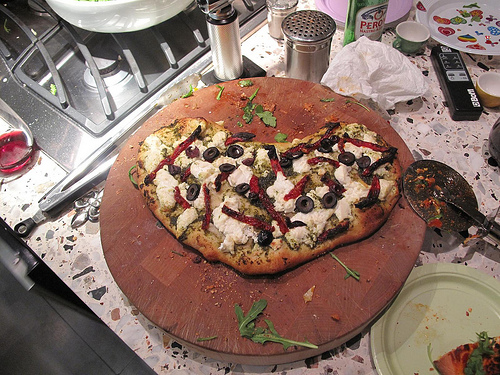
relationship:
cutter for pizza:
[394, 152, 499, 249] [130, 106, 410, 282]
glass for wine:
[1, 99, 45, 202] [1, 129, 38, 177]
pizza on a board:
[130, 106, 410, 282] [91, 73, 436, 371]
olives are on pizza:
[201, 141, 243, 173] [130, 106, 410, 282]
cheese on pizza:
[336, 162, 363, 215] [130, 106, 410, 282]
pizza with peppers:
[130, 106, 410, 282] [249, 180, 288, 232]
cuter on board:
[394, 152, 499, 249] [91, 73, 436, 371]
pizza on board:
[130, 106, 410, 282] [91, 73, 436, 371]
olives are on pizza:
[294, 187, 341, 218] [130, 106, 410, 282]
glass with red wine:
[1, 99, 45, 202] [1, 129, 38, 177]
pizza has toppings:
[130, 106, 410, 282] [163, 137, 385, 228]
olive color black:
[234, 175, 260, 205] [234, 180, 256, 200]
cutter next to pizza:
[394, 152, 499, 249] [130, 106, 410, 282]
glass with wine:
[1, 99, 45, 202] [1, 129, 38, 177]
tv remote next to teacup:
[426, 43, 484, 126] [390, 20, 432, 62]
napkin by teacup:
[318, 32, 434, 111] [390, 20, 432, 62]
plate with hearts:
[413, 0, 499, 60] [430, 13, 481, 48]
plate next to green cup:
[413, 0, 499, 60] [390, 20, 432, 62]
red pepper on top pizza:
[249, 180, 288, 232] [130, 106, 410, 282]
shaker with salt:
[264, 1, 297, 38] [263, 17, 283, 42]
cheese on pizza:
[192, 158, 219, 179] [130, 106, 410, 282]